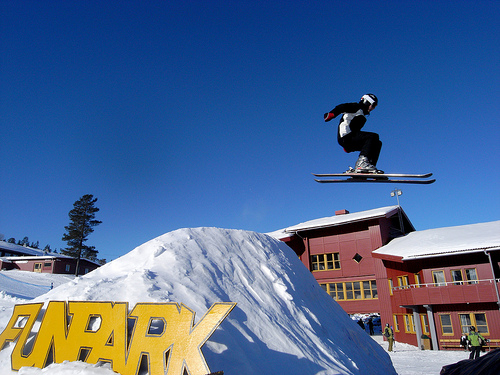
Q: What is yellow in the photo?
A: The sign.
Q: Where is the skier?
A: In the air.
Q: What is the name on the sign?
A: Funpark.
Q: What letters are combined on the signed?
A: The U, N and P.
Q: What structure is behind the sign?
A: A ski jump.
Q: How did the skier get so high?
A: Just cleared the ski jump.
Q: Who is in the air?
A: A skier.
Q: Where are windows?
A: On a building.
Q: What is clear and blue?
A: Sky.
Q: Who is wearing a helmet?
A: The skier.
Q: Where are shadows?
A: On the snow.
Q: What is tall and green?
A: A tree.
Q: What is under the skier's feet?
A: Skis.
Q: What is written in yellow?
A: "FUNPARK".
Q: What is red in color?
A: The building.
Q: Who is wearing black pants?
A: Skier.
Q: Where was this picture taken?
A: Fun Park.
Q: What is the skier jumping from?
A: A mound of snow.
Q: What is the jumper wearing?
A: A helmet.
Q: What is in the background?
A: A red building.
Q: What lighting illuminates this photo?
A: Natural sunlight.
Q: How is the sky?
A: Clear and a brilliant blue.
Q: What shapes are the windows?
A: Diamond and square.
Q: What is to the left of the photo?
A: Trees and another building.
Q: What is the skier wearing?
A: Gloves.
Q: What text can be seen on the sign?
A: Funpark.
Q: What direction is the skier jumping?
A: To the right.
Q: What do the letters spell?
A: FUNPARK.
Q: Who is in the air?
A: Skier.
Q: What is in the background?
A: A building.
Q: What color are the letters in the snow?
A: Yellow.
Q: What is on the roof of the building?
A: Snow.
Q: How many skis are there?
A: Two.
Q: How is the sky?
A: Cloudless.